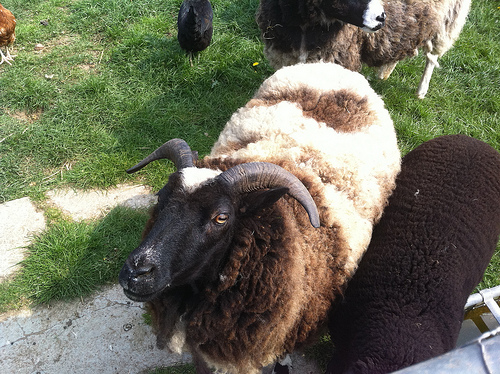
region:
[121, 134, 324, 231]
The horns of the white and black sheep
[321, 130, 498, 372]
The nearest black sheep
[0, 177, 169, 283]
The stones in the grass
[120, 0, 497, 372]
The group of sheep in the photo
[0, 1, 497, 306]
The grass the animals are on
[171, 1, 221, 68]
The black chicken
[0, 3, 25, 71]
The red chicken on the left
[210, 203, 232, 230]
The left eye of the nearest white sheep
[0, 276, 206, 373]
The stone the nearest white sheep is standing on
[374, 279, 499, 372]
The metal object on the right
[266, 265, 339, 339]
a sheep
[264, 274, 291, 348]
a sheep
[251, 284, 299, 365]
a sheep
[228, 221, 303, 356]
a sheep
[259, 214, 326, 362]
a sheep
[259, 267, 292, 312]
a sheep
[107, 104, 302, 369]
Sheep looking at camera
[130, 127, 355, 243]
Sheep has long horns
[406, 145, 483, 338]
The sheep has been shaved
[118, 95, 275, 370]
Sheep has black and white face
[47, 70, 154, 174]
Grass is bushy and green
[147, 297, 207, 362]
The sheep has long chin hair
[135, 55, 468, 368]
Two sheep stand together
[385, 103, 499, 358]
The sheep is black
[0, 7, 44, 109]
Chicken on the grass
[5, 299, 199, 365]
Cracked pavement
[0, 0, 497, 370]
A group of sheep in a grassy area.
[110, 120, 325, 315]
The sheep has two horns.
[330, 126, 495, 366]
A sheep with black wool.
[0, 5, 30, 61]
A brown chicken in the background.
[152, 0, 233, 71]
The chicken is black.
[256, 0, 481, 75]
Part of the sheep is visible.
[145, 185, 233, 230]
The sheep has two eyes.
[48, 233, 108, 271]
A patch of green grass.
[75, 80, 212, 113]
Another patch of green grass.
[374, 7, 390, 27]
The nose of the sheep.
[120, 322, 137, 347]
black mark is spotted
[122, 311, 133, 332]
black mark is spotted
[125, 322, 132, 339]
black mark is spotted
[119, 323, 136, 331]
black mark is spotted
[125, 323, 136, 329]
black mark is spotted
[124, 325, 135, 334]
black mark is spotted